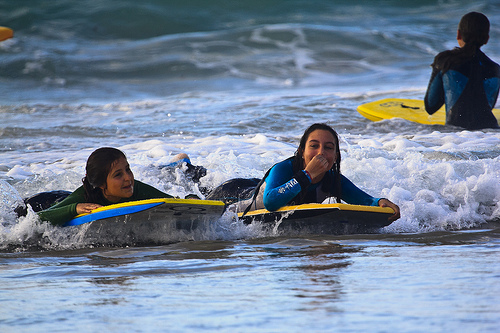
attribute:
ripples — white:
[374, 147, 495, 214]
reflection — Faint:
[268, 240, 378, 316]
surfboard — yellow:
[340, 92, 435, 142]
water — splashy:
[0, 1, 498, 331]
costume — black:
[423, 44, 499, 129]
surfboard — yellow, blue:
[88, 193, 225, 231]